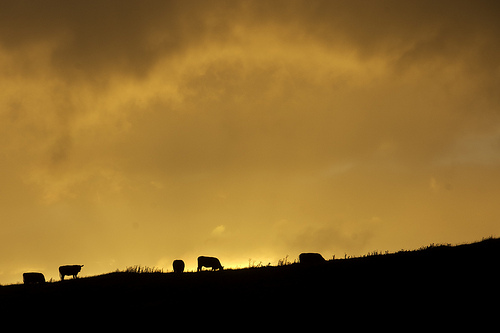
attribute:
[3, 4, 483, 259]
sky — overcasat, golden, peeking, yellow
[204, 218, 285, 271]
sun — going down, bright, setting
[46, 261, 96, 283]
cows — grazing, here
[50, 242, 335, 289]
three cows — eating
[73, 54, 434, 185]
clouds — dark, white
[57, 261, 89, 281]
cow — here